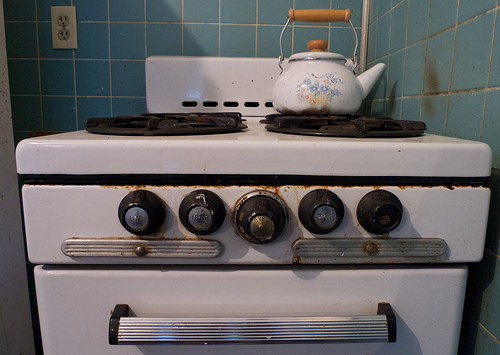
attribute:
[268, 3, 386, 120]
kettle — white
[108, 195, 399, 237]
knobs — black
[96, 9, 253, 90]
wall — tiled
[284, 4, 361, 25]
handle — wooden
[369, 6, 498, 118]
tiles — blue